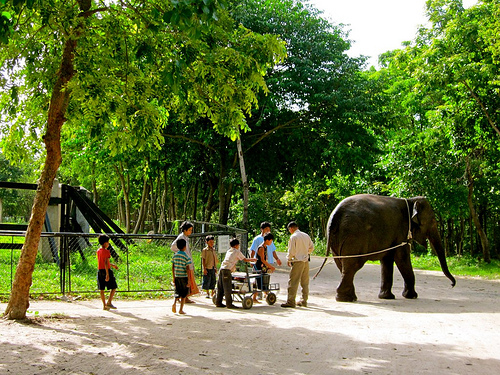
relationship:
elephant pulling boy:
[308, 191, 455, 300] [96, 233, 274, 314]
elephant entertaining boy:
[313, 194, 456, 302] [96, 233, 274, 314]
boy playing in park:
[96, 233, 274, 314] [46, 91, 406, 352]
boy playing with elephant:
[96, 233, 274, 314] [308, 191, 455, 300]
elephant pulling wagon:
[308, 191, 455, 300] [232, 267, 276, 307]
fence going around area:
[0, 220, 249, 295] [2, 221, 246, 294]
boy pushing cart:
[96, 233, 274, 314] [212, 263, 280, 309]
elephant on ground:
[313, 194, 456, 302] [364, 280, 423, 312]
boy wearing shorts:
[93, 237, 136, 309] [95, 270, 115, 290]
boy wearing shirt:
[96, 233, 274, 314] [176, 255, 186, 275]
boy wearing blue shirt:
[96, 233, 274, 314] [250, 235, 276, 263]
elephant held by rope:
[308, 191, 455, 300] [319, 247, 402, 261]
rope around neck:
[402, 196, 413, 243] [395, 192, 423, 249]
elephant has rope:
[324, 190, 460, 305] [402, 196, 413, 243]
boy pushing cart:
[96, 233, 274, 314] [229, 270, 279, 307]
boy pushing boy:
[96, 233, 274, 314] [99, 236, 116, 306]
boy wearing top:
[96, 233, 274, 314] [256, 242, 269, 267]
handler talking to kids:
[281, 221, 314, 308] [191, 226, 298, 308]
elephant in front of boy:
[308, 191, 455, 300] [174, 240, 195, 310]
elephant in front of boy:
[308, 191, 455, 300] [221, 239, 239, 296]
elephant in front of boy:
[308, 191, 455, 300] [198, 235, 215, 286]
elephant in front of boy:
[308, 191, 455, 300] [97, 234, 117, 305]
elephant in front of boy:
[308, 191, 455, 300] [253, 235, 273, 293]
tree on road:
[0, 2, 344, 364] [28, 315, 496, 366]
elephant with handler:
[313, 194, 456, 302] [276, 192, 414, 274]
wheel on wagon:
[255, 282, 287, 314] [216, 270, 288, 320]